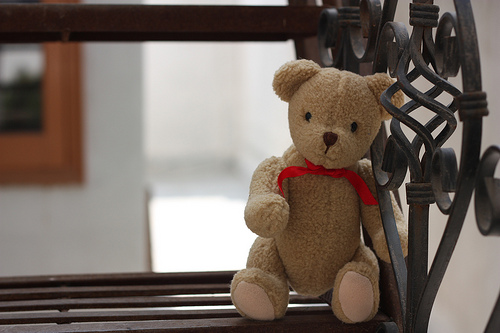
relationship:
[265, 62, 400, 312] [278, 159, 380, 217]
teddy with ribbon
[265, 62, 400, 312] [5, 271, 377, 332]
teddy on bench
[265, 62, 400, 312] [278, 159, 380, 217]
teddy wearing ribbon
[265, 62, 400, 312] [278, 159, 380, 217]
teddy has ribbon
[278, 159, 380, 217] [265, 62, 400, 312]
ribbon on teddy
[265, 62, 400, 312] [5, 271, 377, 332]
teddy sitting on bench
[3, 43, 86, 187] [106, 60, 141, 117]
picture on wall